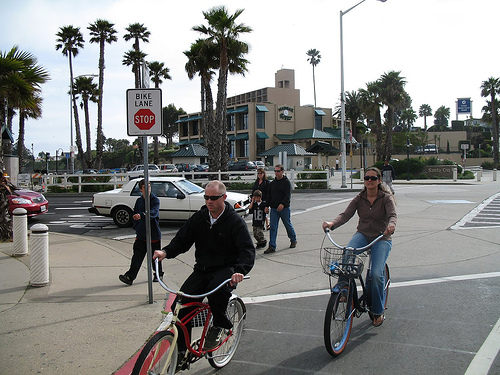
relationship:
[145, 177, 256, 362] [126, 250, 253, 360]
man on a bike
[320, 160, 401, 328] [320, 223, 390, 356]
woman riding a bicycle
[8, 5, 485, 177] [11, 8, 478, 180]
palm trees in the distance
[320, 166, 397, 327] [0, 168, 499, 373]
woman walking on road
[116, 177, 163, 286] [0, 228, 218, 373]
man walking on sidewalk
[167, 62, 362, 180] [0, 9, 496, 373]
building in a city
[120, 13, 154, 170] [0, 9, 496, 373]
tree in a city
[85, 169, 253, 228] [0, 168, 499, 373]
car in a road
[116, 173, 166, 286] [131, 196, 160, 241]
man wearing sweater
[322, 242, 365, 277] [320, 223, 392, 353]
basket on bicycle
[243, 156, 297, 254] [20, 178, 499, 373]
family crossing street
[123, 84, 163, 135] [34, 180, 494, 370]
sign beside road